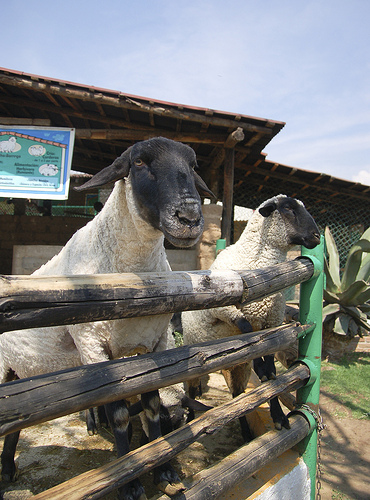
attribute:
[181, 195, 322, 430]
sheep — white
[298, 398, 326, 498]
chain — hanging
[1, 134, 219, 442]
sheep — gazing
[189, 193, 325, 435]
sheep — gazing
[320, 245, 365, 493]
fence — wooden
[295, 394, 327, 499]
chain — hanging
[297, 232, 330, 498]
post — green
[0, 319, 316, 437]
fence post — wood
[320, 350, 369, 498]
shadow — dark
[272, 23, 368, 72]
sky — clear, blue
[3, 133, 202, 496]
sheep — white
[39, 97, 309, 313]
sheep — white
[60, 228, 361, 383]
fence — brown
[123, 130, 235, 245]
sheep face — black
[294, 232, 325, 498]
post — metal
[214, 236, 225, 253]
post — metal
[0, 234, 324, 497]
fence — wood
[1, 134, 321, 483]
sheep — white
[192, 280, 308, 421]
fence — brown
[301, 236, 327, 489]
pole — green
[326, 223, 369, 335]
large leaves — green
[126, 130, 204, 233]
face — black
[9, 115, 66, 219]
sign — behind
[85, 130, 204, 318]
sheep — white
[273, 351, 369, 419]
grass — green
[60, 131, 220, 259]
sheep head — black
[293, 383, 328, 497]
chain — metal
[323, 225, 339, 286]
leaf — large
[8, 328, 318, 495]
wooden fence — weathered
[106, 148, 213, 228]
sheep — white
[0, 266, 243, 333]
post — weathered, wooden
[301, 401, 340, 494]
chain — metal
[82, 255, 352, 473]
bar holder — green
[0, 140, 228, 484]
sheep — white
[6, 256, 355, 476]
fence — is green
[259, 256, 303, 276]
post — wood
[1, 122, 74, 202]
sign — posted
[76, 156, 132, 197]
ear — black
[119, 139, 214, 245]
face — black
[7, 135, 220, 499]
sheep — white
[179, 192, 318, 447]
sheep — white